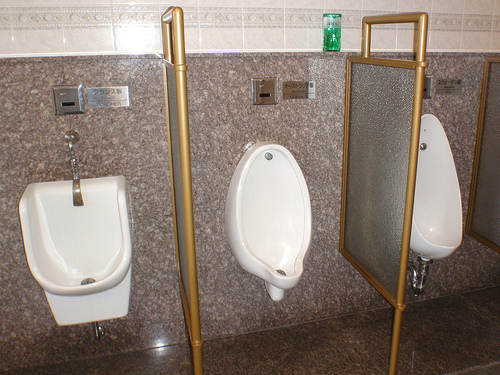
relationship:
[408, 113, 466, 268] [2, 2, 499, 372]
urinal on wall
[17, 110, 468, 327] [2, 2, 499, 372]
three urinals on wall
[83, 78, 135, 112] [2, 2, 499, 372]
metal plate on wall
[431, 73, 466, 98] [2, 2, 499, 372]
metal plate on wall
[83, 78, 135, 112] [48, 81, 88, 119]
metal plate beside mechanism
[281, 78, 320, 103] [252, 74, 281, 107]
metal plate beside mechanism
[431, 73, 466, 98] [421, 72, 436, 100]
metal plate beside mechanism